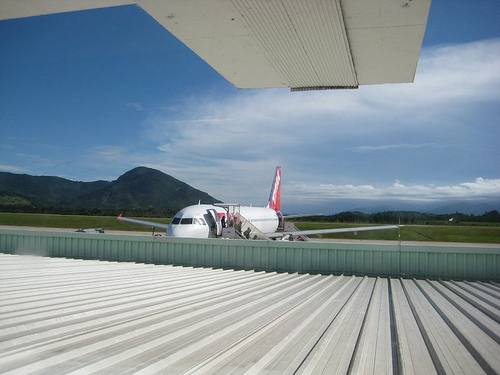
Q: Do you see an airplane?
A: Yes, there is an airplane.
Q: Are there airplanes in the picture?
A: Yes, there is an airplane.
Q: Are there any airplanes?
A: Yes, there is an airplane.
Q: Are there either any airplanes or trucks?
A: Yes, there is an airplane.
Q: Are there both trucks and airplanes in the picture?
A: No, there is an airplane but no trucks.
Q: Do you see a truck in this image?
A: No, there are no trucks.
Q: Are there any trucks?
A: No, there are no trucks.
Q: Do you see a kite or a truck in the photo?
A: No, there are no trucks or kites.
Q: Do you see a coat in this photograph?
A: No, there are no coats.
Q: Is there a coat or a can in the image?
A: No, there are no coats or cans.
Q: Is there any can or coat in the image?
A: No, there are no coats or cans.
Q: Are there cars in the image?
A: No, there are no cars.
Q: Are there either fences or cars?
A: No, there are no cars or fences.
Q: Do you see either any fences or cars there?
A: No, there are no cars or fences.